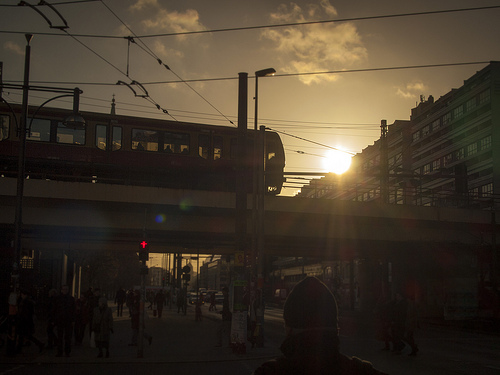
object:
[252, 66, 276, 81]
light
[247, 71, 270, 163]
post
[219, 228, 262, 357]
pole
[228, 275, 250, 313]
posters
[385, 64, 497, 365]
building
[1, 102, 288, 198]
metro train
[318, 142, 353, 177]
setting sun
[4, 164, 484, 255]
monorail bridge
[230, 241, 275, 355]
bridge pillar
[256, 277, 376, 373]
back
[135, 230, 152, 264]
signal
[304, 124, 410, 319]
buildings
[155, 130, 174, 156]
window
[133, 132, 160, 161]
window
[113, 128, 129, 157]
window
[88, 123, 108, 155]
window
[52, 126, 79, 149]
window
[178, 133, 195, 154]
window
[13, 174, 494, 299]
track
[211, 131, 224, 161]
windows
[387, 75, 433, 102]
clouds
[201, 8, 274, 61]
sky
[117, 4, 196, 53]
clouds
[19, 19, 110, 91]
railing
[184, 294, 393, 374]
road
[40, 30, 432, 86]
cables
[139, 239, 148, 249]
light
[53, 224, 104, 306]
tree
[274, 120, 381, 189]
powerlines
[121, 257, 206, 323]
pedestrians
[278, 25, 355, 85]
clouds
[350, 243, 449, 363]
people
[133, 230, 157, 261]
cross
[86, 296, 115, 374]
lady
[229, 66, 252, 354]
pole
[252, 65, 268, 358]
pole